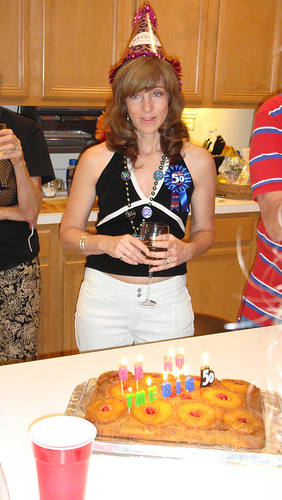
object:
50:
[200, 366, 215, 388]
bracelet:
[79, 232, 90, 255]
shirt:
[84, 127, 196, 281]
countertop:
[36, 192, 259, 227]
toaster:
[21, 110, 103, 152]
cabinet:
[0, 1, 281, 107]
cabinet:
[36, 192, 262, 350]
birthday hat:
[108, 4, 182, 82]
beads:
[120, 144, 166, 239]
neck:
[129, 125, 162, 157]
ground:
[181, 108, 253, 146]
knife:
[210, 134, 226, 172]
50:
[170, 171, 184, 183]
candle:
[125, 395, 133, 411]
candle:
[135, 389, 145, 407]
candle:
[148, 386, 157, 404]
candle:
[162, 384, 171, 397]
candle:
[176, 379, 182, 394]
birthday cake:
[84, 365, 266, 450]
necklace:
[119, 144, 168, 238]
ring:
[167, 259, 170, 265]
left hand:
[144, 233, 186, 273]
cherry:
[146, 405, 155, 417]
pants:
[72, 266, 198, 352]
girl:
[59, 0, 216, 353]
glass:
[135, 222, 170, 310]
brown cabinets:
[213, 10, 245, 84]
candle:
[200, 366, 217, 387]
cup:
[28, 414, 97, 498]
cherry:
[214, 391, 226, 399]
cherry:
[237, 416, 247, 423]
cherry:
[189, 408, 200, 416]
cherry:
[144, 405, 153, 415]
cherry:
[100, 405, 108, 412]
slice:
[201, 387, 244, 409]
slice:
[222, 408, 262, 433]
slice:
[178, 401, 216, 427]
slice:
[132, 396, 172, 425]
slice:
[86, 397, 125, 424]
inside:
[42, 413, 77, 430]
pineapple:
[177, 401, 214, 426]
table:
[0, 317, 282, 500]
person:
[225, 88, 281, 335]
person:
[0, 102, 56, 369]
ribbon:
[162, 163, 194, 215]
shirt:
[237, 94, 282, 324]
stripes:
[247, 122, 282, 198]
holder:
[195, 142, 223, 178]